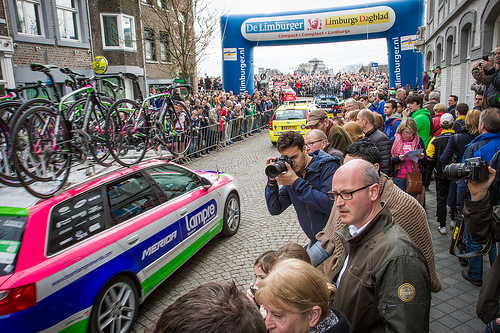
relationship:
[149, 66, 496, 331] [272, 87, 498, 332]
people on roadside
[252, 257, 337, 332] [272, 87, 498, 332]
person on roadside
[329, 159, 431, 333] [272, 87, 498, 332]
man on roadside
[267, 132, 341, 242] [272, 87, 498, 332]
person on roadside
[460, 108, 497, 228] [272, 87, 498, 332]
person on roadside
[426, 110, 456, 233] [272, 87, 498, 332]
person on roadside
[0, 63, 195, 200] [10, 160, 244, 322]
bicycle on car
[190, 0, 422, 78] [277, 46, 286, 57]
sky has clouds